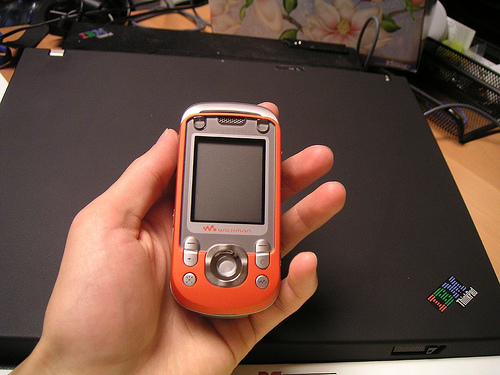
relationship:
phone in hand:
[170, 99, 279, 317] [40, 100, 350, 367]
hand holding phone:
[40, 100, 350, 367] [170, 99, 279, 317]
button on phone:
[181, 236, 199, 267] [170, 99, 279, 317]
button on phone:
[207, 245, 248, 287] [170, 99, 279, 317]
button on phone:
[252, 239, 274, 271] [170, 99, 279, 317]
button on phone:
[255, 274, 270, 291] [170, 99, 279, 317]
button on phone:
[183, 272, 197, 287] [170, 99, 279, 317]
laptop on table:
[357, 85, 500, 353] [468, 138, 500, 215]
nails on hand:
[150, 126, 174, 149] [40, 100, 350, 367]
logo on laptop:
[423, 274, 483, 320] [357, 85, 500, 353]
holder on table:
[422, 39, 499, 137] [0, 0, 500, 284]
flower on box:
[297, 2, 393, 52] [210, 1, 426, 67]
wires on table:
[131, 1, 207, 31] [468, 138, 500, 215]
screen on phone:
[193, 134, 273, 226] [170, 99, 279, 317]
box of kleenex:
[210, 1, 426, 67] [384, 55, 410, 73]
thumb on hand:
[88, 128, 178, 235] [40, 100, 350, 367]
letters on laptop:
[453, 287, 484, 312] [357, 85, 500, 353]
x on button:
[185, 273, 194, 285] [183, 272, 197, 287]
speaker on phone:
[217, 118, 246, 127] [170, 99, 279, 317]